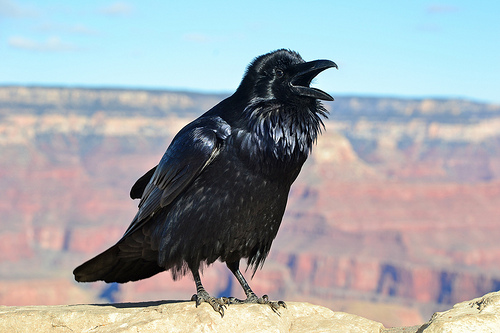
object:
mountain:
[3, 85, 498, 332]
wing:
[119, 114, 224, 242]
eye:
[273, 67, 287, 78]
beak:
[287, 60, 339, 102]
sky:
[2, 3, 500, 101]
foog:
[190, 290, 231, 316]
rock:
[0, 290, 498, 331]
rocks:
[1, 84, 499, 302]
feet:
[188, 285, 288, 316]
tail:
[70, 227, 164, 291]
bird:
[71, 44, 344, 315]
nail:
[216, 304, 225, 314]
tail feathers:
[71, 236, 158, 286]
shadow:
[89, 294, 182, 314]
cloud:
[1, 5, 228, 55]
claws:
[198, 290, 291, 320]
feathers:
[76, 100, 321, 285]